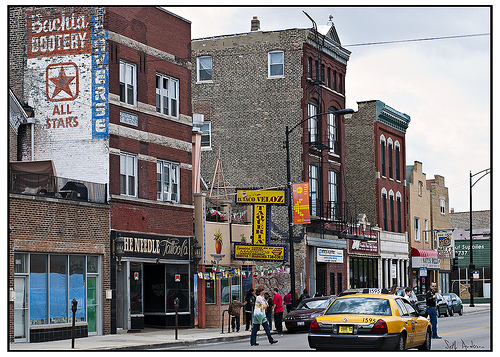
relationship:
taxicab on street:
[310, 279, 432, 347] [174, 292, 479, 353]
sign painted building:
[28, 10, 111, 140] [11, 10, 202, 330]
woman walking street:
[246, 284, 276, 345] [152, 300, 483, 348]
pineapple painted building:
[212, 228, 225, 253] [200, 34, 353, 292]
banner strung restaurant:
[292, 182, 310, 225] [194, 216, 279, 326]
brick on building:
[196, 17, 345, 325] [196, 14, 355, 309]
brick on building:
[196, 17, 345, 325] [200, 27, 349, 321]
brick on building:
[196, 17, 345, 325] [191, 7, 348, 314]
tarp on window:
[28, 273, 91, 318] [28, 250, 51, 328]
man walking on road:
[250, 284, 279, 344] [424, 300, 489, 354]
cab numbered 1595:
[304, 288, 436, 351] [360, 317, 380, 324]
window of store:
[86, 255, 100, 336] [10, 199, 111, 340]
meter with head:
[70, 297, 79, 353] [70, 299, 79, 315]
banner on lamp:
[292, 182, 310, 225] [282, 108, 351, 304]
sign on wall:
[28, 13, 111, 140] [11, 2, 32, 162]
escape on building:
[315, 31, 325, 161] [302, 8, 351, 302]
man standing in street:
[426, 280, 442, 340] [424, 302, 489, 347]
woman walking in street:
[246, 284, 276, 345] [122, 328, 311, 349]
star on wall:
[48, 62, 75, 100] [8, 11, 29, 161]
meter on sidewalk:
[173, 295, 185, 342] [11, 330, 236, 344]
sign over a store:
[113, 231, 202, 259] [88, 11, 215, 342]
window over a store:
[113, 144, 138, 196] [77, 0, 217, 345]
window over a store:
[156, 158, 187, 210] [77, 0, 217, 345]